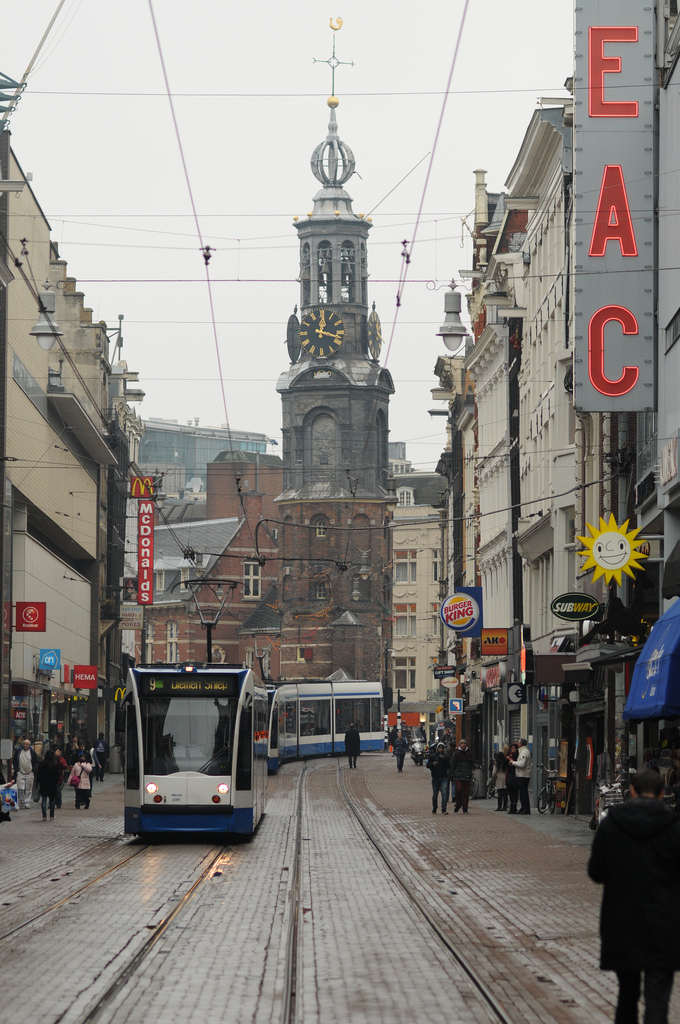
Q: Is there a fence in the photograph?
A: No, there are no fences.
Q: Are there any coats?
A: Yes, there is a coat.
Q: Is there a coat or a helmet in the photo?
A: Yes, there is a coat.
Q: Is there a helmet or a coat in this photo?
A: Yes, there is a coat.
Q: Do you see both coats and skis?
A: No, there is a coat but no skis.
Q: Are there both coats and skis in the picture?
A: No, there is a coat but no skis.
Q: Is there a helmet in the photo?
A: No, there are no helmets.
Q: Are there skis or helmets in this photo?
A: No, there are no helmets or skis.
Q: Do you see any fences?
A: No, there are no fences.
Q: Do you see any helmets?
A: No, there are no helmets.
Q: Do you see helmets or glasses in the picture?
A: No, there are no helmets or glasses.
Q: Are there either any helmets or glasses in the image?
A: No, there are no helmets or glasses.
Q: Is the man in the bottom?
A: Yes, the man is in the bottom of the image.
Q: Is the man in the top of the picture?
A: No, the man is in the bottom of the image.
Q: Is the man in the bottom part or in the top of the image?
A: The man is in the bottom of the image.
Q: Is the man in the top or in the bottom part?
A: The man is in the bottom of the image.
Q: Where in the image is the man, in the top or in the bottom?
A: The man is in the bottom of the image.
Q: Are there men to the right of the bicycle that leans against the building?
A: Yes, there is a man to the right of the bicycle.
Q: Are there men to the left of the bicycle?
A: No, the man is to the right of the bicycle.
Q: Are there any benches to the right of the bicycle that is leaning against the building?
A: No, there is a man to the right of the bicycle.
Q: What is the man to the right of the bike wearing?
A: The man is wearing a coat.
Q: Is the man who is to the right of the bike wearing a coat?
A: Yes, the man is wearing a coat.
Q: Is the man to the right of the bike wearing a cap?
A: No, the man is wearing a coat.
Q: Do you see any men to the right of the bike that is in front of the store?
A: Yes, there is a man to the right of the bike.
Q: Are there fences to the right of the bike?
A: No, there is a man to the right of the bike.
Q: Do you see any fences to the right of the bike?
A: No, there is a man to the right of the bike.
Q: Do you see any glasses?
A: No, there are no glasses.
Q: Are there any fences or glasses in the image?
A: No, there are no glasses or fences.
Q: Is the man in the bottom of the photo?
A: Yes, the man is in the bottom of the image.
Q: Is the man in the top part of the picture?
A: No, the man is in the bottom of the image.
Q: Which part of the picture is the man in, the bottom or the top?
A: The man is in the bottom of the image.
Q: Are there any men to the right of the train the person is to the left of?
A: Yes, there is a man to the right of the train.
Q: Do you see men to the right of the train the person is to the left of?
A: Yes, there is a man to the right of the train.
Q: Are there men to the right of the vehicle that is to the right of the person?
A: Yes, there is a man to the right of the train.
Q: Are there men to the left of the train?
A: No, the man is to the right of the train.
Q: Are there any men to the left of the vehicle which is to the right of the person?
A: No, the man is to the right of the train.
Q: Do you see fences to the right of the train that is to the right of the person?
A: No, there is a man to the right of the train.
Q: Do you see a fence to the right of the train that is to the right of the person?
A: No, there is a man to the right of the train.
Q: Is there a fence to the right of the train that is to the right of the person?
A: No, there is a man to the right of the train.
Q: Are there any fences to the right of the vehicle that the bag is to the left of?
A: No, there is a man to the right of the train.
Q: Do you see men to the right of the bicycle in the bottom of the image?
A: Yes, there is a man to the right of the bicycle.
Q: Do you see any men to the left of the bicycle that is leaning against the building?
A: No, the man is to the right of the bicycle.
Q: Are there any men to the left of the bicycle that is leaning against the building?
A: No, the man is to the right of the bicycle.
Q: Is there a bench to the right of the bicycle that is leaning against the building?
A: No, there is a man to the right of the bicycle.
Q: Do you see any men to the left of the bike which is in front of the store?
A: Yes, there is a man to the left of the bike.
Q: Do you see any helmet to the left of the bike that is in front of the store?
A: No, there is a man to the left of the bike.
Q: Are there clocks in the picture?
A: Yes, there is a clock.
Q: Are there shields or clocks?
A: Yes, there is a clock.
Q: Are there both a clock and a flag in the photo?
A: No, there is a clock but no flags.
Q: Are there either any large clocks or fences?
A: Yes, there is a large clock.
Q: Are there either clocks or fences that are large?
A: Yes, the clock is large.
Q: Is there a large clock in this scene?
A: Yes, there is a large clock.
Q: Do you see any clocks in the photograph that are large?
A: Yes, there is a clock that is large.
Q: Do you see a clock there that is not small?
A: Yes, there is a large clock.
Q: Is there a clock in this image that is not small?
A: Yes, there is a large clock.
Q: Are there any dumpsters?
A: No, there are no dumpsters.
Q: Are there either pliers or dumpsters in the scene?
A: No, there are no dumpsters or pliers.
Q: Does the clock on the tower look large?
A: Yes, the clock is large.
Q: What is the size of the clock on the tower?
A: The clock is large.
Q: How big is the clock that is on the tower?
A: The clock is large.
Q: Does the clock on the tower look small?
A: No, the clock is large.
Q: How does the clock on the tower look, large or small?
A: The clock is large.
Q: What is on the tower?
A: The clock is on the tower.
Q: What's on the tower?
A: The clock is on the tower.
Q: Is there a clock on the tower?
A: Yes, there is a clock on the tower.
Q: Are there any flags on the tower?
A: No, there is a clock on the tower.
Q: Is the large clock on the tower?
A: Yes, the clock is on the tower.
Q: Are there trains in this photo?
A: Yes, there is a train.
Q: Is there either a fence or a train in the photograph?
A: Yes, there is a train.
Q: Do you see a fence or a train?
A: Yes, there is a train.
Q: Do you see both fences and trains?
A: No, there is a train but no fences.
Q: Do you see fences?
A: No, there are no fences.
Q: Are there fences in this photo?
A: No, there are no fences.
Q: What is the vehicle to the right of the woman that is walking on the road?
A: The vehicle is a train.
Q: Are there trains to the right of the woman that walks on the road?
A: Yes, there is a train to the right of the woman.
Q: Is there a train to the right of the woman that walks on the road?
A: Yes, there is a train to the right of the woman.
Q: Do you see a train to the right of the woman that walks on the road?
A: Yes, there is a train to the right of the woman.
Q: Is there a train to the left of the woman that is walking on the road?
A: No, the train is to the right of the woman.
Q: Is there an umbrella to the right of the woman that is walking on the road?
A: No, there is a train to the right of the woman.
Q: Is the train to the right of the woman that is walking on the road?
A: Yes, the train is to the right of the woman.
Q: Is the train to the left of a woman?
A: No, the train is to the right of a woman.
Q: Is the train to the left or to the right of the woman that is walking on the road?
A: The train is to the right of the woman.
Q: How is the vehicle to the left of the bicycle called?
A: The vehicle is a train.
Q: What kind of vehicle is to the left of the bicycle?
A: The vehicle is a train.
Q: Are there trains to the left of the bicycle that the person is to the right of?
A: Yes, there is a train to the left of the bicycle.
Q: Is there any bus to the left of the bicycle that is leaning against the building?
A: No, there is a train to the left of the bicycle.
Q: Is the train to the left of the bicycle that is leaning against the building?
A: Yes, the train is to the left of the bicycle.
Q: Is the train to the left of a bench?
A: No, the train is to the left of the bicycle.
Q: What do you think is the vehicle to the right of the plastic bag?
A: The vehicle is a train.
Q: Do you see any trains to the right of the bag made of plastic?
A: Yes, there is a train to the right of the bag.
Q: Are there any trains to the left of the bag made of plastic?
A: No, the train is to the right of the bag.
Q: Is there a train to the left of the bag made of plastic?
A: No, the train is to the right of the bag.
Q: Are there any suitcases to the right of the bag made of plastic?
A: No, there is a train to the right of the bag.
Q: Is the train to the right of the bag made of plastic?
A: Yes, the train is to the right of the bag.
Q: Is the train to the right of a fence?
A: No, the train is to the right of the bag.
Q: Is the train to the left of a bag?
A: No, the train is to the right of a bag.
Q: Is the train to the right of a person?
A: Yes, the train is to the right of a person.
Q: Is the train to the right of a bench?
A: No, the train is to the right of a person.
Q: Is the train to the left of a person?
A: No, the train is to the right of a person.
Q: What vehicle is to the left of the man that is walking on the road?
A: The vehicle is a train.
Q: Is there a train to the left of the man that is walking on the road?
A: Yes, there is a train to the left of the man.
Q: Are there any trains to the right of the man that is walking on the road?
A: No, the train is to the left of the man.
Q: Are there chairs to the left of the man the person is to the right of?
A: No, there is a train to the left of the man.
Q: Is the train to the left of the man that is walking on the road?
A: Yes, the train is to the left of the man.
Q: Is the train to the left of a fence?
A: No, the train is to the left of the man.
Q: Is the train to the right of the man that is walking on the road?
A: No, the train is to the left of the man.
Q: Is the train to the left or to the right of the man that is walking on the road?
A: The train is to the left of the man.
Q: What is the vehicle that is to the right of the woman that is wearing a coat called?
A: The vehicle is a train.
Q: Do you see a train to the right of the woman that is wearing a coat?
A: Yes, there is a train to the right of the woman.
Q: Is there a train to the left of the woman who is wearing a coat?
A: No, the train is to the right of the woman.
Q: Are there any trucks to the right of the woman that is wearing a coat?
A: No, there is a train to the right of the woman.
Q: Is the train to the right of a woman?
A: Yes, the train is to the right of a woman.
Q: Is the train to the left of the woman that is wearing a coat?
A: No, the train is to the right of the woman.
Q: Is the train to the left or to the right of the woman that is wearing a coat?
A: The train is to the right of the woman.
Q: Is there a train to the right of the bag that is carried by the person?
A: Yes, there is a train to the right of the bag.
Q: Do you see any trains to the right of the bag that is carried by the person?
A: Yes, there is a train to the right of the bag.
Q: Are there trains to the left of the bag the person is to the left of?
A: No, the train is to the right of the bag.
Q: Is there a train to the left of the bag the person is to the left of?
A: No, the train is to the right of the bag.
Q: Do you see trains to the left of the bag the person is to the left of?
A: No, the train is to the right of the bag.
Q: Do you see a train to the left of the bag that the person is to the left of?
A: No, the train is to the right of the bag.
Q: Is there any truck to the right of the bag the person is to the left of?
A: No, there is a train to the right of the bag.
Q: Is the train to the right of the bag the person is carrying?
A: Yes, the train is to the right of the bag.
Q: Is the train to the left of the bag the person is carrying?
A: No, the train is to the right of the bag.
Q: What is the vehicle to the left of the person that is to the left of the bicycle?
A: The vehicle is a train.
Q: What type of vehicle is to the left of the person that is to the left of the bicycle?
A: The vehicle is a train.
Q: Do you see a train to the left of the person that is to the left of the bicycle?
A: Yes, there is a train to the left of the person.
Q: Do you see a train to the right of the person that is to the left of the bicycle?
A: No, the train is to the left of the person.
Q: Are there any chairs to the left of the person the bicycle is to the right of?
A: No, there is a train to the left of the person.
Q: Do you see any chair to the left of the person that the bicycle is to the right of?
A: No, there is a train to the left of the person.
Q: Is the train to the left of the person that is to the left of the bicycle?
A: Yes, the train is to the left of the person.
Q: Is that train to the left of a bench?
A: No, the train is to the left of the person.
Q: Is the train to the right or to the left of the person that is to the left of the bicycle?
A: The train is to the left of the person.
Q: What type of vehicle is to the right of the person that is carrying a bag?
A: The vehicle is a train.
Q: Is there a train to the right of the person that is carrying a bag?
A: Yes, there is a train to the right of the person.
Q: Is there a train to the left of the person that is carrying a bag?
A: No, the train is to the right of the person.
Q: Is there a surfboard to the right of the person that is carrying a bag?
A: No, there is a train to the right of the person.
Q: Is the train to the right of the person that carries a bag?
A: Yes, the train is to the right of the person.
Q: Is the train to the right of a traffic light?
A: No, the train is to the right of the person.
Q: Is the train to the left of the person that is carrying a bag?
A: No, the train is to the right of the person.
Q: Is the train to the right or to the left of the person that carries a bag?
A: The train is to the right of the person.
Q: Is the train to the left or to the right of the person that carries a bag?
A: The train is to the right of the person.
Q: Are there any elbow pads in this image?
A: No, there are no elbow pads.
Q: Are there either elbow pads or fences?
A: No, there are no elbow pads or fences.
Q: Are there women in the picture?
A: Yes, there is a woman.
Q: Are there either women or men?
A: Yes, there is a woman.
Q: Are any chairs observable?
A: No, there are no chairs.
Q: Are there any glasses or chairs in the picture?
A: No, there are no chairs or glasses.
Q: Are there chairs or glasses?
A: No, there are no chairs or glasses.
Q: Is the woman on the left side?
A: Yes, the woman is on the left of the image.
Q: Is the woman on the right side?
A: No, the woman is on the left of the image.